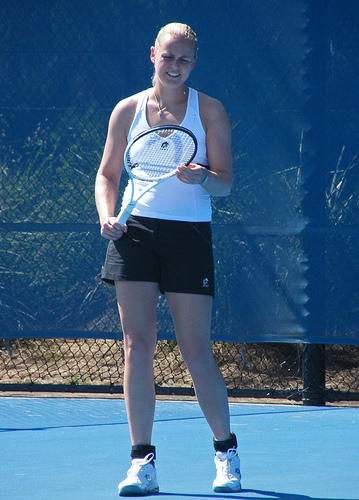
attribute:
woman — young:
[93, 23, 242, 498]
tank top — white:
[121, 85, 213, 223]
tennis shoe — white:
[120, 454, 160, 495]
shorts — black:
[100, 213, 215, 297]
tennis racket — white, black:
[117, 124, 199, 225]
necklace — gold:
[152, 86, 186, 118]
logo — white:
[201, 277, 211, 287]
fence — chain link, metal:
[1, 1, 359, 407]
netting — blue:
[1, 1, 357, 348]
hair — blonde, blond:
[152, 22, 199, 88]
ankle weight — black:
[130, 444, 157, 460]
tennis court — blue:
[0, 396, 358, 498]